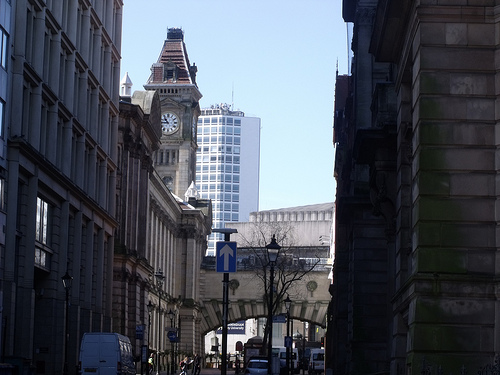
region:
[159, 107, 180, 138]
a clock on the tower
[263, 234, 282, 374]
a park lamp and post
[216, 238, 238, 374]
a pedestrian traffic sign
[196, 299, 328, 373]
an archway between the buildings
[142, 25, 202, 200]
a clock tower in the city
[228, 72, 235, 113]
a communication antenna on the roof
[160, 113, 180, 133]
white clock face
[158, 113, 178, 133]
roman numerals on clock face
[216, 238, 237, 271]
blue sign with white arrow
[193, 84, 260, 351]
white sky scraper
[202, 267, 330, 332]
tan bridge and arch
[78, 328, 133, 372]
white cargo van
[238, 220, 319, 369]
tree in front of bridge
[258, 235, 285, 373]
lamp on a post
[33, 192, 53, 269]
window on the left building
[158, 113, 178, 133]
clock shows the time at 10:46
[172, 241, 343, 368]
passageway connecting buildings across a street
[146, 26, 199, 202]
building tower with a white clock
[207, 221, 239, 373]
white arrow on blue sign on pole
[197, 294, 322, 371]
arched entryway with stone decoration on top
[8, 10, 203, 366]
dark buildings with vertical architecture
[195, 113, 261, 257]
gray building with square windows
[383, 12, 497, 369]
worn and dark stones on corner building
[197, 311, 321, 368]
vehicles beneath archway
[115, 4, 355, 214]
clear blue sky over city providing some light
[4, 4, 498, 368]
Exterior, city view, daytime, vegetation suggestive of winter, or fall.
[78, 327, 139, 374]
White van, seen from back.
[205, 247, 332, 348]
Archway with intricate carving on bridge with train atop.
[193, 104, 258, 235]
Modern, highrise, in distance.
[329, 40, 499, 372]
Weathered, brick siding on elderly building.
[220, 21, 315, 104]
Pale, blue winterish sky.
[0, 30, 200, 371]
Elderly buildings and clock-tower, fronting street.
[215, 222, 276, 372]
Old-fashioned streetlight and pole with sign, showing arrow.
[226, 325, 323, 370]
Traffic, passing under archway.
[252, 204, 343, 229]
Grey, low-roofed building, in distance.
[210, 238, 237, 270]
blue and white sign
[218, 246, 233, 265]
white arrow on blue background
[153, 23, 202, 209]
clock tower in the distance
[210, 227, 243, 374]
black pole sign is on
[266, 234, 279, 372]
black street lamp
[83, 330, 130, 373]
white van driving down the street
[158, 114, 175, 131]
clock with white face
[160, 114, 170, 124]
black minute and hour hands on the clock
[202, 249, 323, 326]
bridge over the street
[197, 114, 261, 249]
white building with reflective windows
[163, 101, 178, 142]
A clock on the building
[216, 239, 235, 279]
A road sign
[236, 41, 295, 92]
Clouds in the skies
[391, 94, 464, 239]
A tall building in the city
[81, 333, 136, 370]
white van parked near huge building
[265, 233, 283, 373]
tall, black lamp post posted on the street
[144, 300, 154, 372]
tall, black lamp post posted on the street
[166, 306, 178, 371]
tall, black lamp post posted on the street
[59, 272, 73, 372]
tall, black lamp post posted on the street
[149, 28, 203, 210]
tall building with a clock on the top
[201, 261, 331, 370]
cement overhang above many vehicles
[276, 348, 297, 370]
white van parked under overhang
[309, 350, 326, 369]
white van parked under overhang